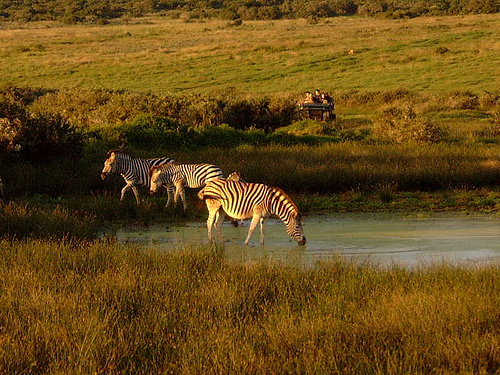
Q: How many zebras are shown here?
A: Three.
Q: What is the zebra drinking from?
A: A watering hole.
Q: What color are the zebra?
A: Black and white.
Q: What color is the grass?
A: Green.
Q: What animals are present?
A: Zebras.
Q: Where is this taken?
A: In a field.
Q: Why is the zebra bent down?
A: To drink.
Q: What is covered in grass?
A: The hillside.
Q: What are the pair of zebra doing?
A: Walking.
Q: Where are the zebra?
A: In natural habitat.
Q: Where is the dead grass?
A: On the field.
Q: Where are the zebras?
A: A watering hole.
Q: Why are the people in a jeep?
A: To look at zebras.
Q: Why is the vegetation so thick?
A: Its near water.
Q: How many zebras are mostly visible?
A: 3.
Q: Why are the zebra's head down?
A: To get a drink.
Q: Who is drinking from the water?
A: Zebras.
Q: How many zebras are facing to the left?
A: 2.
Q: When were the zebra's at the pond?
A: In the afternoon.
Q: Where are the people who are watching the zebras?
A: In a jeep.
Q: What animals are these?
A: Zebras.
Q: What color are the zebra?
A: Black and white.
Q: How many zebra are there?
A: Three.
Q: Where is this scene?
A: A watering hole.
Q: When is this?
A: Daytime.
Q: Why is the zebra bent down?
A: It is drinking.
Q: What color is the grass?
A: Green.